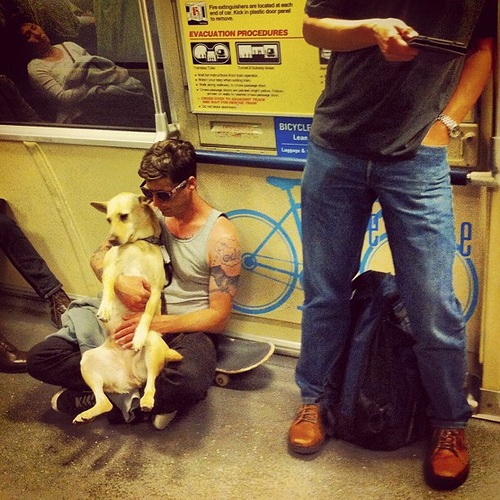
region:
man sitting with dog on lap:
[84, 120, 263, 392]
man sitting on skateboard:
[124, 124, 279, 384]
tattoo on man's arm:
[204, 255, 244, 305]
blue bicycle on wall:
[209, 176, 499, 348]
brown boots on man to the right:
[280, 399, 357, 480]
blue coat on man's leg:
[67, 285, 110, 339]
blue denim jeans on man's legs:
[379, 236, 489, 357]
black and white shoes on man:
[36, 381, 103, 429]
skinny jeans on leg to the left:
[5, 205, 61, 267]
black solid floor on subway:
[72, 427, 284, 497]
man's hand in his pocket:
[421, 1, 496, 157]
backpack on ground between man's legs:
[292, 261, 471, 479]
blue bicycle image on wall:
[221, 167, 480, 326]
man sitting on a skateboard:
[83, 138, 276, 383]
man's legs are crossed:
[25, 325, 215, 410]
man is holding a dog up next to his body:
[70, 140, 241, 428]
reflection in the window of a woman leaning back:
[4, 1, 165, 142]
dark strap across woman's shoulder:
[54, 39, 77, 66]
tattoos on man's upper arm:
[202, 229, 241, 297]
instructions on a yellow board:
[178, 1, 298, 109]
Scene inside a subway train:
[6, 0, 486, 492]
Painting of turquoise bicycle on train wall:
[192, 149, 479, 347]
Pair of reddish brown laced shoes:
[279, 392, 471, 492]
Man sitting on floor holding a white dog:
[6, 120, 248, 445]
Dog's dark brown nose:
[102, 232, 127, 254]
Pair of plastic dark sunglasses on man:
[132, 174, 202, 212]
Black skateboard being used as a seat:
[48, 289, 276, 399]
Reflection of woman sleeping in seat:
[6, 10, 154, 139]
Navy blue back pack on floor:
[309, 269, 471, 454]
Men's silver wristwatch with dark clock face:
[426, 110, 468, 144]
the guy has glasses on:
[127, 156, 267, 437]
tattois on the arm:
[211, 236, 243, 310]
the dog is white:
[78, 205, 210, 398]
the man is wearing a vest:
[29, 165, 254, 426]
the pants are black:
[154, 330, 249, 419]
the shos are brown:
[282, 400, 340, 460]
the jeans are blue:
[303, 150, 480, 430]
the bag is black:
[353, 287, 424, 452]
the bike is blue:
[235, 187, 498, 323]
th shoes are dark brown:
[0, 340, 27, 376]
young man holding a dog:
[23, 138, 242, 431]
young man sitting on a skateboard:
[22, 137, 247, 437]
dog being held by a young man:
[71, 191, 183, 427]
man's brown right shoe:
[283, 398, 332, 457]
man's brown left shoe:
[423, 419, 475, 492]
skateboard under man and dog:
[204, 327, 274, 391]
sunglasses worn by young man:
[138, 178, 191, 205]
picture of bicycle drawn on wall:
[221, 175, 478, 330]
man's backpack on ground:
[330, 268, 432, 450]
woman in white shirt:
[4, 15, 151, 128]